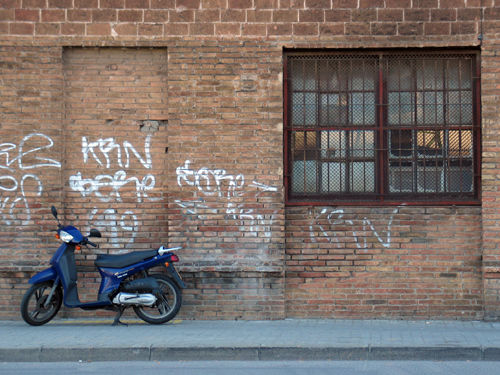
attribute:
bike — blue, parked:
[19, 208, 187, 339]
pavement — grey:
[4, 318, 496, 373]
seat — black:
[93, 252, 158, 270]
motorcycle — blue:
[21, 204, 186, 326]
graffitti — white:
[1, 131, 406, 258]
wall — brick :
[2, 0, 498, 320]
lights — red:
[166, 251, 182, 266]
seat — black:
[91, 236, 171, 285]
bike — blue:
[16, 205, 192, 322]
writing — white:
[55, 120, 212, 252]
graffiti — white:
[3, 130, 280, 252]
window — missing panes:
[277, 39, 484, 210]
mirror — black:
[49, 204, 58, 216]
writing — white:
[58, 130, 165, 242]